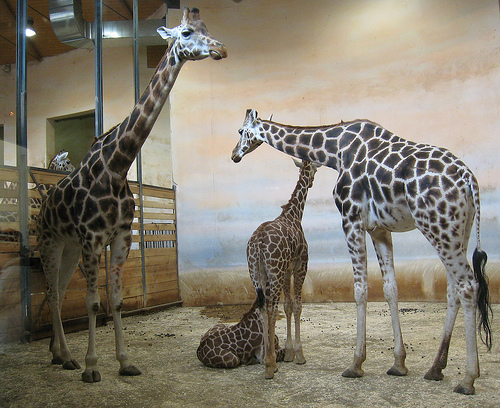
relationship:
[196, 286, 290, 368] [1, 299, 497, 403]
giraffe on ground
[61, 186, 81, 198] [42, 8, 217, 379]
spot on giraffe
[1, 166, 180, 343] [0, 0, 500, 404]
wooden enclosure on giraffe pen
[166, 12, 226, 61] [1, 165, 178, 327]
head from nearby enclosure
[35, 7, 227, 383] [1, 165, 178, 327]
giraffe from nearby enclosure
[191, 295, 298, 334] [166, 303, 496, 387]
stain on floor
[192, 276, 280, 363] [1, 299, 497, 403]
giraffe sitting on ground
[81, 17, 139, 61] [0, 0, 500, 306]
light in wall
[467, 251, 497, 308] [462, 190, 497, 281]
hair on tail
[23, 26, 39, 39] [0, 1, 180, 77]
light on ceiling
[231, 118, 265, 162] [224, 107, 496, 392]
face of giraffe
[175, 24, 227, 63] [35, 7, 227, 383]
face of giraffe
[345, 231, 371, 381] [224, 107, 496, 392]
leg of giraffe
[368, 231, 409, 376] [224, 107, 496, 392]
leg of giraffe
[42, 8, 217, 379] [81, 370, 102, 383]
giraffe has clove-hoof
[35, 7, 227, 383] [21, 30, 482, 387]
giraffe in a pen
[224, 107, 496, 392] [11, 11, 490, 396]
giraffe in a pen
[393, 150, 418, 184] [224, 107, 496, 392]
spot on a giraffe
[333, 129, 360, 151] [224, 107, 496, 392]
spot on a giraffe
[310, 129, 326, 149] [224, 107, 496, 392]
spot on a giraffe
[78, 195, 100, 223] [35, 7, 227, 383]
spot on a giraffe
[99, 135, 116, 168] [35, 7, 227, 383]
spot on a giraffe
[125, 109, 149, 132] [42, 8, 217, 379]
spot on giraffe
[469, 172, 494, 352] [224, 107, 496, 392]
tail of giraffe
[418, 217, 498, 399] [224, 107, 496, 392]
leg of giraffe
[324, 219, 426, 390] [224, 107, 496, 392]
legs of giraffe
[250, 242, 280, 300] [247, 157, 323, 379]
tail of giraffe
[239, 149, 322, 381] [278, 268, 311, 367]
giraffe of legs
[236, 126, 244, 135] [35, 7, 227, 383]
eye of giraffe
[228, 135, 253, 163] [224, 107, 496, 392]
mouth of giraffe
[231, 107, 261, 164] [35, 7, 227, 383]
head of giraffe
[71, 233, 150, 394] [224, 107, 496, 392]
legs of giraffe